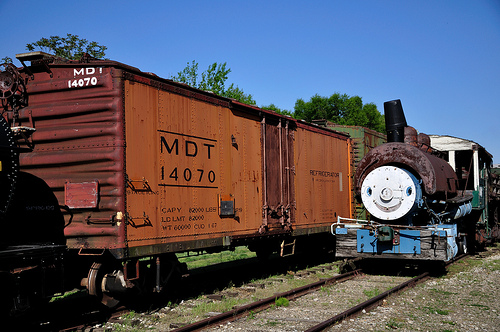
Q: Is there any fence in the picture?
A: No, there are no fences.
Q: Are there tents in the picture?
A: No, there are no tents.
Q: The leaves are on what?
A: The leaves are on the tree.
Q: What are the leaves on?
A: The leaves are on the tree.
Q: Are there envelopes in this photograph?
A: No, there are no envelopes.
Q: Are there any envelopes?
A: No, there are no envelopes.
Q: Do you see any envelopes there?
A: No, there are no envelopes.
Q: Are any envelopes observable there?
A: No, there are no envelopes.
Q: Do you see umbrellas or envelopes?
A: No, there are no envelopes or umbrellas.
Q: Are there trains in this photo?
A: Yes, there is a train.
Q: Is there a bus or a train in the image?
A: Yes, there is a train.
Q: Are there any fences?
A: No, there are no fences.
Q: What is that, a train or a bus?
A: That is a train.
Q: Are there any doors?
A: Yes, there is a door.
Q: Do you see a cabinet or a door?
A: Yes, there is a door.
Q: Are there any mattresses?
A: No, there are no mattresses.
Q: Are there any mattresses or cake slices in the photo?
A: No, there are no mattresses or cake slices.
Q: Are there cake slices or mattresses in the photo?
A: No, there are no mattresses or cake slices.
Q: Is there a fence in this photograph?
A: No, there are no fences.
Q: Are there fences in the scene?
A: No, there are no fences.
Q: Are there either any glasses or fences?
A: No, there are no fences or glasses.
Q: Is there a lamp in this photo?
A: No, there are no lamps.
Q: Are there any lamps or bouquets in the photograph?
A: No, there are no lamps or bouquets.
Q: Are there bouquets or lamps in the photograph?
A: No, there are no lamps or bouquets.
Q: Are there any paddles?
A: No, there are no paddles.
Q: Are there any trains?
A: Yes, there is a train.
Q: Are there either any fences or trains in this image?
A: Yes, there is a train.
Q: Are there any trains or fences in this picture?
A: Yes, there is a train.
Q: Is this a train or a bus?
A: This is a train.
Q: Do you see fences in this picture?
A: No, there are no fences.